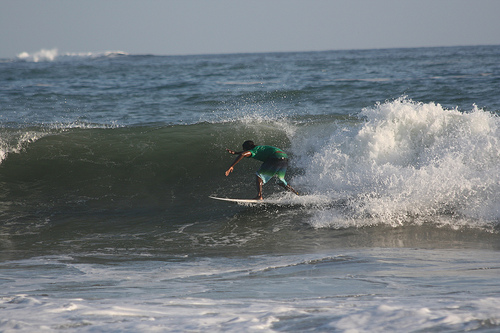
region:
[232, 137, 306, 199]
the person is in green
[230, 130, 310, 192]
the person is a man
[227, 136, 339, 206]
the person is a surfer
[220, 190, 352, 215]
the surfboard is white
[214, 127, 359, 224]
the surfer is on board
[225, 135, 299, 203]
the man is tan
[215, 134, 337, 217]
the man is surfing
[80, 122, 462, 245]
the wave is behind man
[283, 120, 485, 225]
the wave foam is white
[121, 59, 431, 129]
the water is blue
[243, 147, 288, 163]
Green shirt on surfer.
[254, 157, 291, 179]
Green shorts on surfer.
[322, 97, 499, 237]
Wave foamy and high.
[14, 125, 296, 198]
Wave soon to overtake surfer.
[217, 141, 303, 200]
Surfer on board in ocean.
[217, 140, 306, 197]
Young boy on surf board bending forward.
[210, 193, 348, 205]
White surf board partially submerged in water.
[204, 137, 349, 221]
Young man on surfboard in ocean.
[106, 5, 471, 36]
Blue and overcast sky.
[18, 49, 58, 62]
Waves foaming up in background.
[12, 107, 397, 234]
a moderate sized wave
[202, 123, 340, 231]
a surfer getting ready to catch a wave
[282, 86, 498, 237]
turbulent water after a wave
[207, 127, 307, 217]
a man in green shorts and a green shirt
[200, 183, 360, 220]
a white surfboard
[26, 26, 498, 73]
the ocean horizon line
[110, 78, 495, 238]
a crashing wave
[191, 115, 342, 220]
a surfboarder standing on a surfboard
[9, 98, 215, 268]
a growing ocean wave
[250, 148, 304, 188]
swimming trunks that fade from black to green then to blue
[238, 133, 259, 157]
the head of a man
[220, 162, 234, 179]
the hand of a man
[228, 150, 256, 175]
the arm of a man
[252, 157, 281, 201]
the leg of a man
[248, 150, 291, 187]
a pair of green shorts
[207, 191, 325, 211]
a white surfboard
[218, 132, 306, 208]
a man on the skateboard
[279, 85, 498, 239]
a white foaming wave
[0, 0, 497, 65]
a gray sky over the water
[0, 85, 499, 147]
the crest of a wave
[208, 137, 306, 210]
a man riding a surfboard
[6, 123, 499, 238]
the wave the man is riding on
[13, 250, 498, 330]
part of the massive ocean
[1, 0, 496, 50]
the sky above the ocean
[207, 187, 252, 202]
the surfboard the man is riding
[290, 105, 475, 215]
the wave that is crashing over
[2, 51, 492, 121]
another part of the ocean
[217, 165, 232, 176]
the man's hand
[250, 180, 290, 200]
the man's legs on the surfboard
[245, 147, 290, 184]
the wetsuit the man is wearing